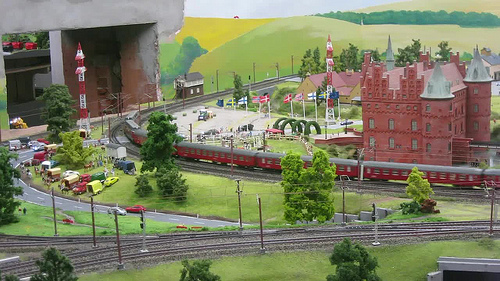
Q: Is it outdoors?
A: Yes, it is outdoors.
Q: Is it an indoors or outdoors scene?
A: It is outdoors.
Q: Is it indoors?
A: No, it is outdoors.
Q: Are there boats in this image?
A: No, there are no boats.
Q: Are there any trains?
A: Yes, there is a train.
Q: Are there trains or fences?
A: Yes, there is a train.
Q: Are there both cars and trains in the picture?
A: Yes, there are both a train and a car.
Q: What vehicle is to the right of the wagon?
A: The vehicle is a train.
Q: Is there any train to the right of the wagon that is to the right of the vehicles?
A: Yes, there is a train to the right of the wagon.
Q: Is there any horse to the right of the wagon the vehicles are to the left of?
A: No, there is a train to the right of the wagon.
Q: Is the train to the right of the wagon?
A: Yes, the train is to the right of the wagon.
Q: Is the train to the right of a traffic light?
A: No, the train is to the right of the wagon.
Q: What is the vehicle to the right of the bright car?
A: The vehicle is a train.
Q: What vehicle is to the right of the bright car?
A: The vehicle is a train.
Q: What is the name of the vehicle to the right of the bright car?
A: The vehicle is a train.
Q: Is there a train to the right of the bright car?
A: Yes, there is a train to the right of the car.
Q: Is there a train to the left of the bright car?
A: No, the train is to the right of the car.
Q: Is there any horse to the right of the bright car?
A: No, there is a train to the right of the car.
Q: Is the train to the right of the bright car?
A: Yes, the train is to the right of the car.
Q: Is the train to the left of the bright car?
A: No, the train is to the right of the car.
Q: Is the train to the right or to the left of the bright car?
A: The train is to the right of the car.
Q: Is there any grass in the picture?
A: Yes, there is grass.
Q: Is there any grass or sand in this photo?
A: Yes, there is grass.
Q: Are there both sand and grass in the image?
A: No, there is grass but no sand.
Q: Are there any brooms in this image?
A: No, there are no brooms.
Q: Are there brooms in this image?
A: No, there are no brooms.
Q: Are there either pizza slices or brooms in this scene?
A: No, there are no brooms or pizza slices.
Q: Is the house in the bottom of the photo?
A: No, the house is in the top of the image.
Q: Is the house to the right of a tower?
A: Yes, the house is to the right of a tower.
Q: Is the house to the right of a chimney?
A: No, the house is to the right of a tower.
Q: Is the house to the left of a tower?
A: No, the house is to the right of a tower.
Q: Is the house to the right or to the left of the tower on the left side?
A: The house is to the right of the tower.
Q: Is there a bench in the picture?
A: No, there are no benches.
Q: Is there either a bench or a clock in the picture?
A: No, there are no benches or clocks.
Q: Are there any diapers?
A: No, there are no diapers.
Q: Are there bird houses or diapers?
A: No, there are no diapers or bird houses.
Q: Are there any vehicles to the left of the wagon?
A: Yes, there are vehicles to the left of the wagon.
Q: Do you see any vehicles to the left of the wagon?
A: Yes, there are vehicles to the left of the wagon.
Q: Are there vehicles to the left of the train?
A: Yes, there are vehicles to the left of the train.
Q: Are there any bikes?
A: No, there are no bikes.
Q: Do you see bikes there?
A: No, there are no bikes.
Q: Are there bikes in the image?
A: No, there are no bikes.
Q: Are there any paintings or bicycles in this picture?
A: No, there are no bicycles or paintings.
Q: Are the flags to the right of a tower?
A: Yes, the flags are to the right of a tower.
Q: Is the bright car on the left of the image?
A: Yes, the car is on the left of the image.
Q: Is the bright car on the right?
A: No, the car is on the left of the image.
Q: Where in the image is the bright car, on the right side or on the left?
A: The car is on the left of the image.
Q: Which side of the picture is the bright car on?
A: The car is on the left of the image.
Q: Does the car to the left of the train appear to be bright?
A: Yes, the car is bright.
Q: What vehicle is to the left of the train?
A: The vehicle is a car.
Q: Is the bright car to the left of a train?
A: Yes, the car is to the left of a train.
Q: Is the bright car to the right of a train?
A: No, the car is to the left of a train.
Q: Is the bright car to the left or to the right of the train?
A: The car is to the left of the train.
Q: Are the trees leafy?
A: Yes, the trees are leafy.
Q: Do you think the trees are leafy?
A: Yes, the trees are leafy.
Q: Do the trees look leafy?
A: Yes, the trees are leafy.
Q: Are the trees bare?
A: No, the trees are leafy.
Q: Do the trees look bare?
A: No, the trees are leafy.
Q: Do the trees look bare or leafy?
A: The trees are leafy.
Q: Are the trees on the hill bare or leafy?
A: The trees are leafy.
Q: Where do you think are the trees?
A: The trees are on the hill.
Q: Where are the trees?
A: The trees are on the hill.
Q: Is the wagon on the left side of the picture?
A: Yes, the wagon is on the left of the image.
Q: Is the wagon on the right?
A: No, the wagon is on the left of the image.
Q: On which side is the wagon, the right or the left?
A: The wagon is on the left of the image.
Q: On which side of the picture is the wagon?
A: The wagon is on the left of the image.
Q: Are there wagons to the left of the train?
A: Yes, there is a wagon to the left of the train.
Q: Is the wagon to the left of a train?
A: Yes, the wagon is to the left of a train.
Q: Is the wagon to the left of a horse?
A: No, the wagon is to the left of a train.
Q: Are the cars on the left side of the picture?
A: Yes, the cars are on the left of the image.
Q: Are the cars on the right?
A: No, the cars are on the left of the image.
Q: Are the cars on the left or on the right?
A: The cars are on the left of the image.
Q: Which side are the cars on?
A: The cars are on the left of the image.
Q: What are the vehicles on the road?
A: The vehicles are cars.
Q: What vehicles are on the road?
A: The vehicles are cars.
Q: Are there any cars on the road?
A: Yes, there are cars on the road.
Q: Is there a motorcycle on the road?
A: No, there are cars on the road.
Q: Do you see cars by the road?
A: Yes, there are cars by the road.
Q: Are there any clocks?
A: No, there are no clocks.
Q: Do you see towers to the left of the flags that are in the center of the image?
A: Yes, there is a tower to the left of the flags.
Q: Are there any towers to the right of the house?
A: No, the tower is to the left of the house.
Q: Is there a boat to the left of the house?
A: No, there is a tower to the left of the house.